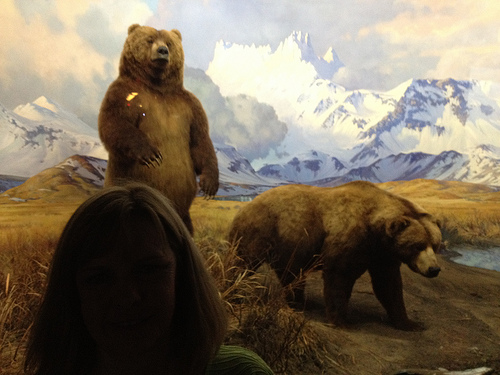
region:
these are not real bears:
[51, 2, 465, 337]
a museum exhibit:
[1, 0, 496, 373]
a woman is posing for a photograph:
[21, 161, 308, 369]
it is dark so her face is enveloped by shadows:
[28, 165, 292, 373]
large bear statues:
[89, 5, 466, 350]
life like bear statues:
[90, 12, 474, 349]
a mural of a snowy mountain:
[3, 1, 497, 188]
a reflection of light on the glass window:
[107, 78, 162, 123]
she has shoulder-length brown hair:
[28, 173, 241, 369]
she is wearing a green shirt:
[216, 337, 285, 374]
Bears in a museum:
[35, 8, 495, 348]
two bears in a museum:
[69, 12, 474, 314]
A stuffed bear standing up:
[73, 11, 217, 288]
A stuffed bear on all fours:
[216, 156, 453, 338]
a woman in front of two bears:
[28, 180, 286, 374]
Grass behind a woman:
[198, 233, 323, 365]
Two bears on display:
[78, 21, 456, 328]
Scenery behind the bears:
[10, 10, 499, 212]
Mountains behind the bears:
[10, 22, 492, 227]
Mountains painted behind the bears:
[10, 8, 498, 225]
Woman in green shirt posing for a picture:
[17, 175, 277, 371]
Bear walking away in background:
[225, 180, 460, 330]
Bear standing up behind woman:
[15, 15, 275, 370]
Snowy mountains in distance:
[0, 32, 495, 182]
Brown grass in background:
[0, 165, 495, 245]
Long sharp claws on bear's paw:
[110, 140, 226, 197]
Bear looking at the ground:
[230, 181, 450, 328]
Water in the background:
[442, 230, 497, 275]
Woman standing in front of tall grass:
[0, 177, 270, 369]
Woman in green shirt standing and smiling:
[5, 185, 270, 374]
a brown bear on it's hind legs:
[98, 15, 216, 228]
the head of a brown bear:
[116, 18, 191, 84]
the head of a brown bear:
[371, 191, 448, 291]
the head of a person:
[38, 182, 222, 370]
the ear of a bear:
[124, 17, 141, 34]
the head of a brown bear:
[168, 25, 187, 40]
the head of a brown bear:
[385, 210, 412, 238]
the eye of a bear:
[414, 240, 426, 255]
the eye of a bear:
[143, 33, 157, 48]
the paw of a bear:
[123, 137, 166, 174]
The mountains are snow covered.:
[24, 40, 487, 172]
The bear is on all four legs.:
[242, 167, 457, 343]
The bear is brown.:
[225, 179, 454, 324]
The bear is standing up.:
[98, 10, 226, 235]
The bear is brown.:
[97, 17, 231, 241]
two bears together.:
[84, 20, 466, 322]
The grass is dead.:
[0, 198, 333, 368]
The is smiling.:
[28, 191, 255, 366]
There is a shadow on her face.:
[43, 190, 238, 370]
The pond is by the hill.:
[447, 232, 498, 284]